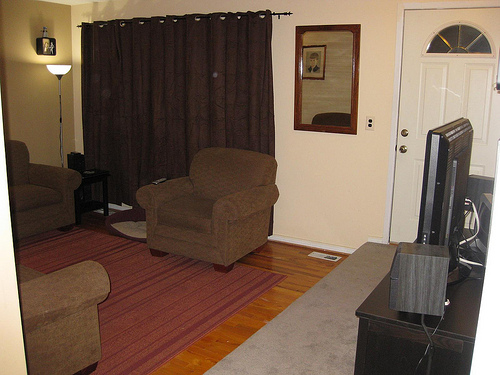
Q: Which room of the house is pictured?
A: It is a living room.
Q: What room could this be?
A: It is a living room.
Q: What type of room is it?
A: It is a living room.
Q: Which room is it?
A: It is a living room.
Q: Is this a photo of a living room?
A: Yes, it is showing a living room.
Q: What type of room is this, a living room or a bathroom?
A: It is a living room.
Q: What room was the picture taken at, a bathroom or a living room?
A: It was taken at a living room.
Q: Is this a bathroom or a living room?
A: It is a living room.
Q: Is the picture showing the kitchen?
A: No, the picture is showing the living room.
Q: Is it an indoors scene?
A: Yes, it is indoors.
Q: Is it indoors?
A: Yes, it is indoors.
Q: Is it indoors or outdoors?
A: It is indoors.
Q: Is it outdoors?
A: No, it is indoors.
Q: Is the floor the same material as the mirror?
A: Yes, both the floor and the mirror are made of wood.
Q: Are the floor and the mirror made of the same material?
A: Yes, both the floor and the mirror are made of wood.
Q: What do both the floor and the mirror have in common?
A: The material, both the floor and the mirror are wooden.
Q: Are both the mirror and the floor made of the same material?
A: Yes, both the mirror and the floor are made of wood.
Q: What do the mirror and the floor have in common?
A: The material, both the mirror and the floor are wooden.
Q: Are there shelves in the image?
A: No, there are no shelves.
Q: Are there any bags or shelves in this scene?
A: No, there are no shelves or bags.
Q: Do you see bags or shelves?
A: No, there are no shelves or bags.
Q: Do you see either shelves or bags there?
A: No, there are no shelves or bags.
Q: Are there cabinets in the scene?
A: No, there are no cabinets.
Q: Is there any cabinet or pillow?
A: No, there are no cabinets or pillows.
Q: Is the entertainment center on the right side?
A: Yes, the entertainment center is on the right of the image.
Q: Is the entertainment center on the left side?
A: No, the entertainment center is on the right of the image.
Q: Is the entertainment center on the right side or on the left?
A: The entertainment center is on the right of the image.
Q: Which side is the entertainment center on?
A: The entertainment center is on the right of the image.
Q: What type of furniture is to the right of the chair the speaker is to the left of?
A: The piece of furniture is an entertainment center.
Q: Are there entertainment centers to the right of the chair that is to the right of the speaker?
A: Yes, there is an entertainment center to the right of the chair.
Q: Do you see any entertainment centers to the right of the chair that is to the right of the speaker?
A: Yes, there is an entertainment center to the right of the chair.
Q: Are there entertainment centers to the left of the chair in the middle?
A: No, the entertainment center is to the right of the chair.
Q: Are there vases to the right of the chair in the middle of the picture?
A: No, there is an entertainment center to the right of the chair.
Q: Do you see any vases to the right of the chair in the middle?
A: No, there is an entertainment center to the right of the chair.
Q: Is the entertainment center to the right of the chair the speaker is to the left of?
A: Yes, the entertainment center is to the right of the chair.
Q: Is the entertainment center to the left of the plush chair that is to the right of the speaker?
A: No, the entertainment center is to the right of the chair.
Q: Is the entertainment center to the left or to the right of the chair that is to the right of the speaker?
A: The entertainment center is to the right of the chair.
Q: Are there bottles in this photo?
A: No, there are no bottles.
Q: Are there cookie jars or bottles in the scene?
A: No, there are no bottles or cookie jars.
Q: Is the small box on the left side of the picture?
A: Yes, the box is on the left of the image.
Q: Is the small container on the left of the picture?
A: Yes, the box is on the left of the image.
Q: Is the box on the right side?
A: No, the box is on the left of the image.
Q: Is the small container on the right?
A: No, the box is on the left of the image.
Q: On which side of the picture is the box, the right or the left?
A: The box is on the left of the image.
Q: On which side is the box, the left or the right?
A: The box is on the left of the image.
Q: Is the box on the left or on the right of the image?
A: The box is on the left of the image.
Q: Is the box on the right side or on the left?
A: The box is on the left of the image.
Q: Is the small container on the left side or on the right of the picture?
A: The box is on the left of the image.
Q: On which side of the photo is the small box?
A: The box is on the left of the image.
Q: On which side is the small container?
A: The box is on the left of the image.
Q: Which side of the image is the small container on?
A: The box is on the left of the image.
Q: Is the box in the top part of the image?
A: Yes, the box is in the top of the image.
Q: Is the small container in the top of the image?
A: Yes, the box is in the top of the image.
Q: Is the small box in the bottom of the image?
A: No, the box is in the top of the image.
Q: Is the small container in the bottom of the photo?
A: No, the box is in the top of the image.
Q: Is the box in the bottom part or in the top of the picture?
A: The box is in the top of the image.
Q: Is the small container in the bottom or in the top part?
A: The box is in the top of the image.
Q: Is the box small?
A: Yes, the box is small.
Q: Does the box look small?
A: Yes, the box is small.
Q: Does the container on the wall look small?
A: Yes, the box is small.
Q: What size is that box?
A: The box is small.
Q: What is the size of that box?
A: The box is small.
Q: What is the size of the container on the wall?
A: The box is small.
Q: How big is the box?
A: The box is small.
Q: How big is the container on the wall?
A: The box is small.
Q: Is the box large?
A: No, the box is small.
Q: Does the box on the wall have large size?
A: No, the box is small.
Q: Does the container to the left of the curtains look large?
A: No, the box is small.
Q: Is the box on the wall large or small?
A: The box is small.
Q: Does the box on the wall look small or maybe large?
A: The box is small.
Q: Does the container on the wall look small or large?
A: The box is small.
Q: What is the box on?
A: The box is on the wall.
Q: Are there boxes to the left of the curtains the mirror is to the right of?
A: Yes, there is a box to the left of the curtains.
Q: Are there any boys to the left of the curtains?
A: No, there is a box to the left of the curtains.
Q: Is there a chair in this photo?
A: Yes, there is a chair.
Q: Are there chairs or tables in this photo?
A: Yes, there is a chair.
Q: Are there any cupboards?
A: No, there are no cupboards.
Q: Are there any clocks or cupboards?
A: No, there are no cupboards or clocks.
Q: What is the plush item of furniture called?
A: The piece of furniture is a chair.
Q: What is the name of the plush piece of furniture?
A: The piece of furniture is a chair.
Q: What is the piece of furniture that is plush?
A: The piece of furniture is a chair.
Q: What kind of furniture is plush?
A: The furniture is a chair.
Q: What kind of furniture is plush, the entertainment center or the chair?
A: The chair is plush.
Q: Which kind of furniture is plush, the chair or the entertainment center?
A: The chair is plush.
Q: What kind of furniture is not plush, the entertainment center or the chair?
A: The entertainment center is not plush.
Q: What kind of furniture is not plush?
A: The furniture is an entertainment center.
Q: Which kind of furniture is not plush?
A: The furniture is an entertainment center.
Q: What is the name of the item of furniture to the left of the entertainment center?
A: The piece of furniture is a chair.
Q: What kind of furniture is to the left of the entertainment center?
A: The piece of furniture is a chair.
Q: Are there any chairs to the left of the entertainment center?
A: Yes, there is a chair to the left of the entertainment center.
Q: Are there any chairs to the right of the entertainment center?
A: No, the chair is to the left of the entertainment center.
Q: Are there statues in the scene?
A: No, there are no statues.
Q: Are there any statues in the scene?
A: No, there are no statues.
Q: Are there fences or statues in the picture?
A: No, there are no statues or fences.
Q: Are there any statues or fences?
A: No, there are no statues or fences.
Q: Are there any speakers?
A: Yes, there is a speaker.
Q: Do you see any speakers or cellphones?
A: Yes, there is a speaker.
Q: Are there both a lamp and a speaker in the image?
A: Yes, there are both a speaker and a lamp.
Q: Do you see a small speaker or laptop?
A: Yes, there is a small speaker.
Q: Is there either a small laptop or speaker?
A: Yes, there is a small speaker.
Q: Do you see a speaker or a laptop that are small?
A: Yes, the speaker is small.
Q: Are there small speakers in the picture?
A: Yes, there is a small speaker.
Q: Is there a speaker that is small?
A: Yes, there is a speaker that is small.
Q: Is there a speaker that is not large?
A: Yes, there is a small speaker.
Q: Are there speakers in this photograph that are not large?
A: Yes, there is a small speaker.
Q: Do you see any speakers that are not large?
A: Yes, there is a small speaker.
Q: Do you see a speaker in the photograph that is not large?
A: Yes, there is a small speaker.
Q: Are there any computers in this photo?
A: No, there are no computers.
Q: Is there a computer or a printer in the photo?
A: No, there are no computers or printers.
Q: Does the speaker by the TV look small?
A: Yes, the speaker is small.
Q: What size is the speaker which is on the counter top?
A: The speaker is small.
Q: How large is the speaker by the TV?
A: The speaker is small.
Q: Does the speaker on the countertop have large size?
A: No, the speaker is small.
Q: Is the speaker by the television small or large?
A: The speaker is small.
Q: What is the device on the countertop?
A: The device is a speaker.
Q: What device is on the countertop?
A: The device is a speaker.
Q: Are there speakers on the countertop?
A: Yes, there is a speaker on the countertop.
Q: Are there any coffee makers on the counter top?
A: No, there is a speaker on the counter top.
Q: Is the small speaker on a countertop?
A: Yes, the speaker is on a countertop.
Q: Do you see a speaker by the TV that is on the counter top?
A: Yes, there is a speaker by the television.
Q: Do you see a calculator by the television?
A: No, there is a speaker by the television.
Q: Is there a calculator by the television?
A: No, there is a speaker by the television.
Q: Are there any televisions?
A: Yes, there is a television.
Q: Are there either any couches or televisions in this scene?
A: Yes, there is a television.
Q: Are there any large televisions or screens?
A: Yes, there is a large television.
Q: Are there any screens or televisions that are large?
A: Yes, the television is large.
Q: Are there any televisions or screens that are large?
A: Yes, the television is large.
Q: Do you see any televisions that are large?
A: Yes, there is a large television.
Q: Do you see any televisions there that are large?
A: Yes, there is a television that is large.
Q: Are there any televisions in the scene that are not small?
A: Yes, there is a large television.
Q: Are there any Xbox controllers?
A: No, there are no Xbox controllers.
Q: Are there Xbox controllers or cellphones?
A: No, there are no Xbox controllers or cellphones.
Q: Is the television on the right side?
A: Yes, the television is on the right of the image.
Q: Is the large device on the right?
A: Yes, the television is on the right of the image.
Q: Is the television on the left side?
A: No, the television is on the right of the image.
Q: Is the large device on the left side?
A: No, the television is on the right of the image.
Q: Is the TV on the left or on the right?
A: The TV is on the right of the image.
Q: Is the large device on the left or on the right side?
A: The TV is on the right of the image.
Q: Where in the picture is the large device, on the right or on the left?
A: The TV is on the right of the image.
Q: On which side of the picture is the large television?
A: The television is on the right of the image.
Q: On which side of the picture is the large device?
A: The television is on the right of the image.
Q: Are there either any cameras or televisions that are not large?
A: No, there is a television but it is large.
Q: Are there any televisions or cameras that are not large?
A: No, there is a television but it is large.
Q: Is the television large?
A: Yes, the television is large.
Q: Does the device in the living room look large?
A: Yes, the TV is large.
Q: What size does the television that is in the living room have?
A: The television has large size.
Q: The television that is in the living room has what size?
A: The television is large.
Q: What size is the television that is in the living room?
A: The television is large.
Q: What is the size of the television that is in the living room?
A: The television is large.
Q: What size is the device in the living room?
A: The television is large.